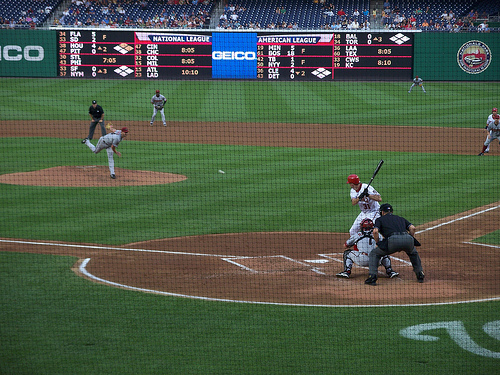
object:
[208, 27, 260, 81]
advertisement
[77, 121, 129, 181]
person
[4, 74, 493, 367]
field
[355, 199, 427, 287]
person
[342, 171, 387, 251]
person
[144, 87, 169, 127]
person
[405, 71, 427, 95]
person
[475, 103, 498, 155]
person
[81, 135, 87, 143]
foot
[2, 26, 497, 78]
wall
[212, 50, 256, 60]
fence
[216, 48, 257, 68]
sign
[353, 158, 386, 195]
bat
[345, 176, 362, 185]
helmet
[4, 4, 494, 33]
people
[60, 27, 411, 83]
board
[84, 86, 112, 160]
man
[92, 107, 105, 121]
shirt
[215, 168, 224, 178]
ball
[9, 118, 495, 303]
dirt